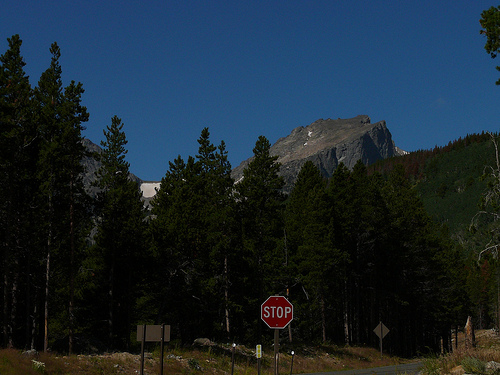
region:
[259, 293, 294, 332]
A red and white stop sign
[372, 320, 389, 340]
The back of a diamond shaped sign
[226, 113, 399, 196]
The top of a mountain sticking up above the trees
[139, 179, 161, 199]
Large snow patch between the trees on a mountain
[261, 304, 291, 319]
The word STOP on a sign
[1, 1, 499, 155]
Dark blue sky above the trees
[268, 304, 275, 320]
The white letter T in STOP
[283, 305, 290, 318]
The white letter P in STOP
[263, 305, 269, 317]
A white letter S in STOP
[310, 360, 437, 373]
A barely visible road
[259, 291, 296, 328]
red and white stop sign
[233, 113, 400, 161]
rocky mountain peak rising above the trees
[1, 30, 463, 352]
green pine trees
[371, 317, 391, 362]
diamond shaped sign on a pole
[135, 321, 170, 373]
rectangular shaped sign on two poles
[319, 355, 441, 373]
gray road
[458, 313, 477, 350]
tree stump next to the road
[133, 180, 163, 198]
white snow on the mountain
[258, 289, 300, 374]
stop sign on a gray road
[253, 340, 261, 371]
small white sign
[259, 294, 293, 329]
A stop sign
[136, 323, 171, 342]
A rectangular shaped sign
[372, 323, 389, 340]
A diamond shaped sign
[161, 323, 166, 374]
A metal post behind a sign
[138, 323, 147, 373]
A metal post behind a sign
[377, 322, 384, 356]
A metal post behind a sign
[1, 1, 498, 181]
A clear blue sky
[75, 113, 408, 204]
A large mountain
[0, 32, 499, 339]
A large wooded landscape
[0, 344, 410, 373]
A small grassy hill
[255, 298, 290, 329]
red and white sign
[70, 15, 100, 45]
white clouds in blue sky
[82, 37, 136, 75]
white clouds in blue sky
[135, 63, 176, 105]
white clouds in blue sky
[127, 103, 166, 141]
white clouds in blue sky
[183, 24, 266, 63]
white clouds in blue sky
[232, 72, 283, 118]
white clouds in blue sky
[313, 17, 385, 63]
white clouds in blue sky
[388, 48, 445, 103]
white clouds in blue sky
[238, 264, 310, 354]
the sign is red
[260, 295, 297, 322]
the letters are white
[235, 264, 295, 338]
the sign is shaped like an octagon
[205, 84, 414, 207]
a rock mountain in the background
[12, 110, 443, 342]
the trees are dark green in a row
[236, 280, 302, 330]
the sign says stop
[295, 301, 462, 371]
the road is empty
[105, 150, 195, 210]
snow on the mountain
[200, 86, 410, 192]
the rock is grey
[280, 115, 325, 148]
a small patch of snow